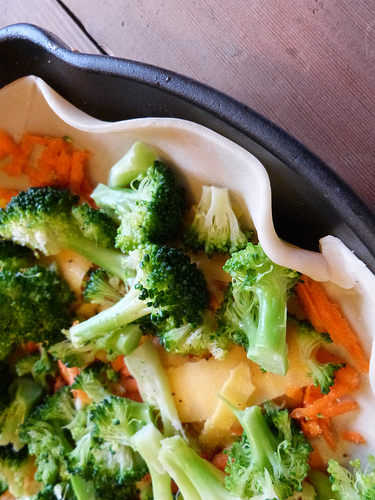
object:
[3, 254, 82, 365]
broccoli spear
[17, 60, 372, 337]
dish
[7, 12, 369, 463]
dish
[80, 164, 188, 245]
broccoli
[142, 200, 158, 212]
green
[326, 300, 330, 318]
small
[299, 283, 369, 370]
carrot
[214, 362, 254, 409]
slice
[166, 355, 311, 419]
cheese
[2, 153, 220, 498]
salad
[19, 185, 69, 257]
vegetables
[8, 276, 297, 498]
food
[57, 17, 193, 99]
pan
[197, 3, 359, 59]
table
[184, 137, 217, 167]
white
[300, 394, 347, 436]
shreds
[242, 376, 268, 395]
dough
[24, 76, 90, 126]
crust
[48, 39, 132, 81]
skillet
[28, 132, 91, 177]
shredded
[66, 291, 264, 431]
mixture